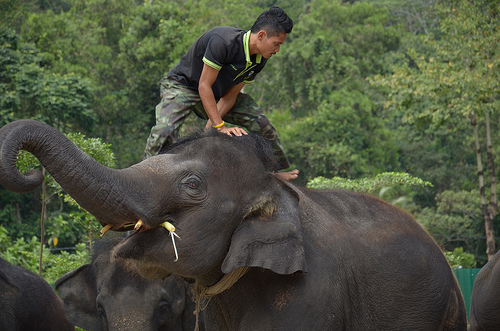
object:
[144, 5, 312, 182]
man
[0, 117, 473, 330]
elephant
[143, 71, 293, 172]
pants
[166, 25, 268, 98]
shirt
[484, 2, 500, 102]
trees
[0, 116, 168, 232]
trunk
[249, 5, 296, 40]
hair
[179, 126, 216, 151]
fur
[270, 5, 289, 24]
haircut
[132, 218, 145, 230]
tusks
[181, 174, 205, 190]
eyes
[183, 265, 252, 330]
cloth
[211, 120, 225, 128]
wristband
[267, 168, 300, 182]
foot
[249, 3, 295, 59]
head